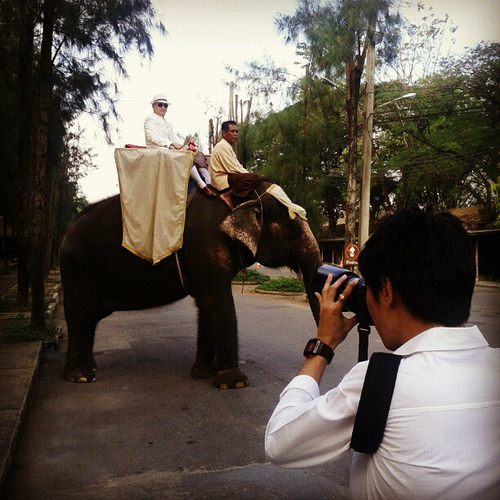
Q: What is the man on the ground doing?
A: Taking picture.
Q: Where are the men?
A: On the elephant.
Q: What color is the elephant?
A: Black.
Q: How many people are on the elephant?
A: 2.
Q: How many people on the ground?
A: 1.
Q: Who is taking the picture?
A: Man with white shirt.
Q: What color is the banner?
A: Yellow.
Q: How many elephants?
A: 1.